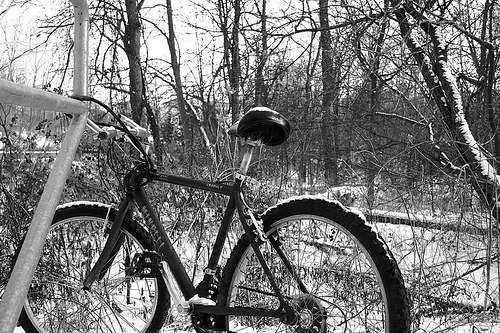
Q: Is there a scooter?
A: No, there are no scooters.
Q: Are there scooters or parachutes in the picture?
A: No, there are no scooters or parachutes.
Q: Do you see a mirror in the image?
A: No, there are no mirrors.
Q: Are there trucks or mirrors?
A: No, there are no mirrors or trucks.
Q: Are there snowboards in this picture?
A: No, there are no snowboards.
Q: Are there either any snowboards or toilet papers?
A: No, there are no snowboards or toilet papers.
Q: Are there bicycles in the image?
A: Yes, there is a bicycle.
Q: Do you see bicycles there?
A: Yes, there is a bicycle.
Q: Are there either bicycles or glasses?
A: Yes, there is a bicycle.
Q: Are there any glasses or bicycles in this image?
A: Yes, there is a bicycle.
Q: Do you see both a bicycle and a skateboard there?
A: No, there is a bicycle but no skateboards.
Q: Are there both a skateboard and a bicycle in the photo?
A: No, there is a bicycle but no skateboards.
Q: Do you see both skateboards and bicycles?
A: No, there is a bicycle but no skateboards.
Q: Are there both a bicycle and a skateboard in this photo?
A: No, there is a bicycle but no skateboards.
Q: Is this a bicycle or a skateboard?
A: This is a bicycle.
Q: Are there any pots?
A: No, there are no pots.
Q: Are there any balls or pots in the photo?
A: No, there are no pots or balls.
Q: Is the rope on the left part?
A: Yes, the rope is on the left of the image.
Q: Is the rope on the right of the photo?
A: No, the rope is on the left of the image.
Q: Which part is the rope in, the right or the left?
A: The rope is on the left of the image.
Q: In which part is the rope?
A: The rope is on the left of the image.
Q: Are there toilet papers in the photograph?
A: No, there are no toilet papers.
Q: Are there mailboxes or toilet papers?
A: No, there are no toilet papers or mailboxes.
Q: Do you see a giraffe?
A: No, there are no giraffes.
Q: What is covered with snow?
A: The tree is covered with snow.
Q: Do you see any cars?
A: No, there are no cars.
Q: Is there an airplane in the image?
A: No, there are no airplanes.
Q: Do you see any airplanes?
A: No, there are no airplanes.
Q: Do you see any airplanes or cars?
A: No, there are no airplanes or cars.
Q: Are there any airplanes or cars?
A: No, there are no airplanes or cars.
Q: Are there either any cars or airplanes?
A: No, there are no airplanes or cars.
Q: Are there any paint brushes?
A: No, there are no paint brushes.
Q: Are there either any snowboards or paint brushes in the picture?
A: No, there are no paint brushes or snowboards.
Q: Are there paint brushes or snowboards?
A: No, there are no paint brushes or snowboards.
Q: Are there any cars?
A: No, there are no cars.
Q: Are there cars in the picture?
A: No, there are no cars.